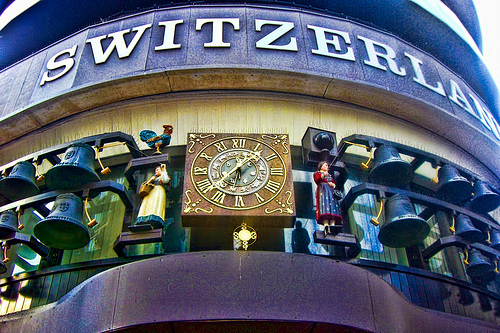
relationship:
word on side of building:
[37, 15, 498, 142] [0, 1, 500, 333]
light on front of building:
[234, 223, 257, 249] [0, 1, 500, 333]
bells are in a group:
[1, 144, 95, 249] [0, 130, 142, 276]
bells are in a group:
[377, 144, 497, 275] [335, 130, 498, 298]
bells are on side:
[1, 144, 95, 249] [1, 2, 185, 333]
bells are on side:
[377, 144, 497, 275] [293, 2, 499, 332]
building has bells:
[0, 1, 500, 333] [1, 144, 95, 249]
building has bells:
[0, 1, 500, 333] [377, 144, 497, 275]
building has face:
[0, 1, 500, 333] [113, 1, 371, 333]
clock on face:
[183, 133, 296, 227] [113, 1, 371, 333]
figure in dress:
[313, 159, 342, 234] [314, 171, 343, 221]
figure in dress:
[130, 165, 173, 227] [314, 171, 343, 221]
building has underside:
[0, 1, 500, 333] [0, 72, 498, 162]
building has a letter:
[0, 1, 500, 333] [255, 20, 299, 53]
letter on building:
[255, 20, 299, 53] [0, 1, 500, 333]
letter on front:
[255, 20, 299, 53] [113, 1, 371, 333]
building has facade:
[0, 1, 500, 333] [2, 116, 499, 308]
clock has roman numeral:
[183, 133, 296, 227] [233, 195, 244, 208]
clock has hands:
[183, 133, 296, 227] [206, 150, 262, 194]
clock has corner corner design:
[183, 133, 296, 227] [188, 134, 218, 154]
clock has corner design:
[183, 133, 296, 227] [262, 132, 292, 155]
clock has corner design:
[183, 133, 296, 227] [184, 191, 215, 217]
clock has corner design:
[183, 133, 296, 227] [264, 191, 295, 217]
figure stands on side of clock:
[313, 159, 342, 234] [183, 133, 296, 227]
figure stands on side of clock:
[130, 165, 173, 227] [183, 133, 296, 227]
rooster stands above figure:
[137, 125, 173, 152] [130, 165, 173, 227]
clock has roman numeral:
[183, 133, 296, 227] [254, 141, 263, 153]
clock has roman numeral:
[183, 133, 296, 227] [264, 152, 280, 162]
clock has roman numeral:
[183, 133, 296, 227] [270, 166, 286, 178]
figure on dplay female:
[313, 159, 342, 234] [318, 160, 330, 177]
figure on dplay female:
[130, 165, 173, 227] [151, 165, 167, 180]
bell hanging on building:
[48, 143, 100, 194] [0, 1, 500, 333]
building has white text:
[0, 1, 500, 333] [37, 15, 498, 142]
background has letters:
[0, 0, 500, 132] [37, 15, 498, 142]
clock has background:
[183, 133, 296, 227] [185, 133, 294, 230]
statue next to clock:
[313, 159, 342, 234] [183, 133, 296, 227]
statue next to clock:
[130, 165, 173, 227] [183, 133, 296, 227]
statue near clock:
[313, 159, 342, 234] [183, 133, 296, 227]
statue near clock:
[130, 165, 173, 227] [183, 133, 296, 227]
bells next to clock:
[1, 144, 95, 249] [183, 133, 296, 227]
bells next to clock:
[377, 144, 497, 275] [183, 133, 296, 227]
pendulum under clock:
[234, 223, 257, 249] [183, 133, 296, 227]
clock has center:
[183, 133, 296, 227] [222, 157, 257, 186]